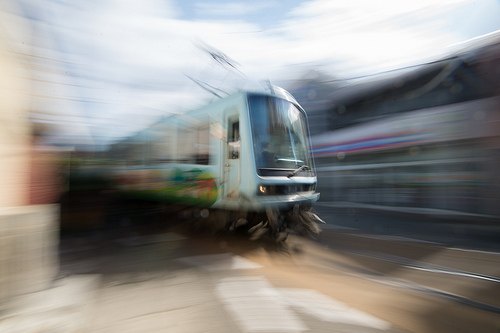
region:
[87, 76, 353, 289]
extremely fast bullet train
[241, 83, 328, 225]
large train windshield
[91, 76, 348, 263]
train on railroad tracks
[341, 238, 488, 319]
railroad tracks with gravel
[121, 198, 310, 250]
wheels of a very fast train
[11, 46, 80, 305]
train depot in a blur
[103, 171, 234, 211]
colorful logo on the side of a train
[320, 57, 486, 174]
speeding train with red and blue stripes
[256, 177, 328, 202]
one headlight on a train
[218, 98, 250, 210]
train door with a window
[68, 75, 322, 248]
The blurry blue train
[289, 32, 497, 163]
The out of focus silver train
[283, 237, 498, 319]
The tracks in front of the blue train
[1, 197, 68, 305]
The short concrete wall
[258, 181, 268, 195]
The headlight of the blue bus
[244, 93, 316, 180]
The blue bus' windshield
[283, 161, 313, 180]
The windshield wiper of the blue bus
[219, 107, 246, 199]
The front door of the blue bus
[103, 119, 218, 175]
The windows on the side of the blue bus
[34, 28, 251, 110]
The wires above the blue bus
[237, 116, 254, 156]
edge of a train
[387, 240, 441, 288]
part of a rail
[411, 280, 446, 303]
edge of a rail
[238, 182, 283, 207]
part of a headlight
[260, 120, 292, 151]
part of a window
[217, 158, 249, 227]
part of a door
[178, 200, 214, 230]
wheels of a train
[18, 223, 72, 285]
part of a stone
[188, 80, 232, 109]
upper edge of a train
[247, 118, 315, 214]
front of a train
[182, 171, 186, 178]
a green color can be seen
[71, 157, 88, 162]
a green color can be seen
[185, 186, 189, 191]
a green color can be seen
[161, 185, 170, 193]
a green color can be seen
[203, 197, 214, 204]
a green color can be seen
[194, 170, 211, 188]
a green color can be seen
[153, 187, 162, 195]
a green color can be seen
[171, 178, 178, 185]
a green color can be seen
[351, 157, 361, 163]
a green color can be seen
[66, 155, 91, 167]
a green color can be seen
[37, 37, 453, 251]
Picture is blury.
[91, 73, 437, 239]
Picture of a train.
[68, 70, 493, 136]
The train is moving.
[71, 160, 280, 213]
The train is colorful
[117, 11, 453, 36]
The sky is blue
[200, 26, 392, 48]
clouds in the sky.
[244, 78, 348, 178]
The train has a window.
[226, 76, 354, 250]
The window is very large.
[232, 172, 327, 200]
The train's lights are on.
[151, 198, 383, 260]
The train is on the tracks.